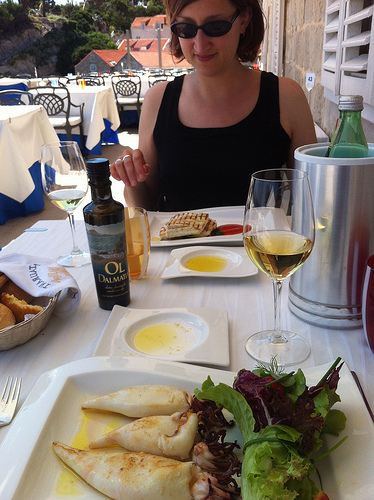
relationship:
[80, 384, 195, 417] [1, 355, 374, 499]
chicken on plate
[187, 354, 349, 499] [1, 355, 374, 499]
greens are on plate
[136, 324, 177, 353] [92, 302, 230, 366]
oil in bowl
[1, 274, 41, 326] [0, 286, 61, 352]
bread in bowl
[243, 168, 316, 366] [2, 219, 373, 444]
glass on table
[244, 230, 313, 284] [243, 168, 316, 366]
wine in glass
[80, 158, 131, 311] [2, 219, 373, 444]
bottle on table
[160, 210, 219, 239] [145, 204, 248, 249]
grilled cheese on plate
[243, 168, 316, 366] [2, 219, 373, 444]
glass sitting on table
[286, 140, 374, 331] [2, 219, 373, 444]
bucket on table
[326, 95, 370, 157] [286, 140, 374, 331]
bottle in bucket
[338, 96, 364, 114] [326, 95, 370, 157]
top on bottle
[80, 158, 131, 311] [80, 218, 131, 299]
bottle has label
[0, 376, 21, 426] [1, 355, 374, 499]
fork next to plate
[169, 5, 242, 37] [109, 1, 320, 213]
sunglasses on lady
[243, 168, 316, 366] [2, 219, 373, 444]
glass sits on table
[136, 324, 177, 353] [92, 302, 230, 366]
oil on bowl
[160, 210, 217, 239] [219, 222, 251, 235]
fish with red sauce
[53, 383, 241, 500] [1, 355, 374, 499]
squid on plate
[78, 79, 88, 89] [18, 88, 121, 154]
candle sitting on table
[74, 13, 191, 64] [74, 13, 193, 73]
roof on house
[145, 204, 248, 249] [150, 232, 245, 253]
plate has edge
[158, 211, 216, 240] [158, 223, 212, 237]
food has edge